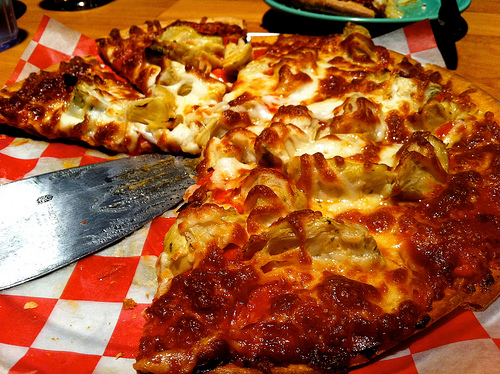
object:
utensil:
[0, 154, 196, 291]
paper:
[14, 132, 144, 347]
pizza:
[0, 16, 499, 372]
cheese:
[184, 40, 288, 126]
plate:
[263, 0, 471, 23]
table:
[443, 5, 492, 73]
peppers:
[321, 278, 369, 311]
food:
[300, 0, 419, 18]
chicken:
[125, 96, 183, 130]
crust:
[116, 16, 258, 28]